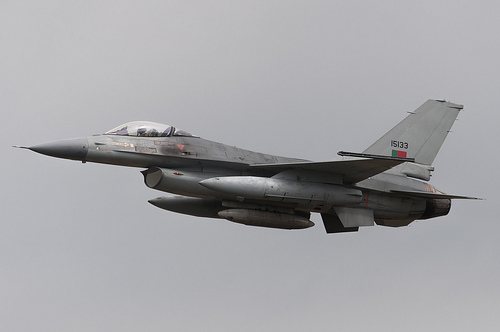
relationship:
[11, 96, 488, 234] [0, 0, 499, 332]
fighter jet in sky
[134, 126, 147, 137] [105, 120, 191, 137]
pilot in cockpit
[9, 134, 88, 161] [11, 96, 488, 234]
nose of fighter jet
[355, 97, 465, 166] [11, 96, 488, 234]
tail of fighter jet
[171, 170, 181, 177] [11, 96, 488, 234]
light on fighter jet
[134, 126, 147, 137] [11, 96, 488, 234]
pilot flying fighter jet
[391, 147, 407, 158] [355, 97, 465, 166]
rectangle on tail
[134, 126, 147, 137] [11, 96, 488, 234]
pilot in fighter jet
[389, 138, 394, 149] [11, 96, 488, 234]
number on fighter jet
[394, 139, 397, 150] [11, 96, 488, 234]
number on fighter jet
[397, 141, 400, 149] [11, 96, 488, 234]
number on fighter jet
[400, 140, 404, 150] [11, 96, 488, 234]
number on fighter jet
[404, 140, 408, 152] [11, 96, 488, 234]
number on fighter jet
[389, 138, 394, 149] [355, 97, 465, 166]
number on tail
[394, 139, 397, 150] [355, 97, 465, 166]
number on tail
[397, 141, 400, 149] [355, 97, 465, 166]
number on tail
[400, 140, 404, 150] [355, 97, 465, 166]
number on tail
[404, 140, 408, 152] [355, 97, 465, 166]
number on tail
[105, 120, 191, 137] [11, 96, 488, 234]
cockpit of fighter jet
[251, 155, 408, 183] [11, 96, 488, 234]
wing of fighter jet